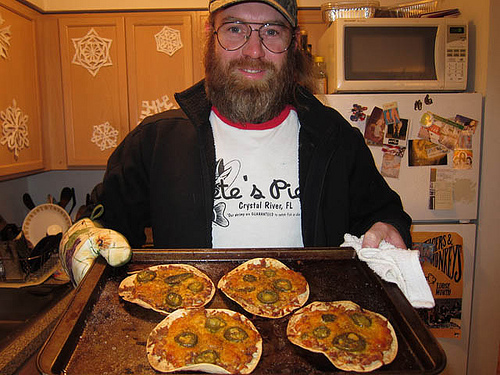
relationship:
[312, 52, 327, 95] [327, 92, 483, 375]
bottle sitting on top fridge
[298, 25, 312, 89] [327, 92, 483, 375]
bottle sitting on top fridge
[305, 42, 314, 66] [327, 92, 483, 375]
bottle sitting on top fridge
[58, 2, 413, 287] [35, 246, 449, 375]
man holding pan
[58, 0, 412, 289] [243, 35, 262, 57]
man has nose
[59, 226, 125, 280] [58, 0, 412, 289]
hand of man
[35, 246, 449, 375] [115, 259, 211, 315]
pan with pizza toritlla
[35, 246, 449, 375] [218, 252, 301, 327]
pan with pizza toritlla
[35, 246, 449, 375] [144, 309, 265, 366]
pan with pizza toritlla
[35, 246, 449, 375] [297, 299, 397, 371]
pan with pizza toritlla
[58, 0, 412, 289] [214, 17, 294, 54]
man wearing glasses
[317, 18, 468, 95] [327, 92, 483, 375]
microwave on top of fridge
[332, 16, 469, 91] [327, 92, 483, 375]
microwave sitting on fridge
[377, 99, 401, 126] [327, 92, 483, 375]
magnet stuck on fridge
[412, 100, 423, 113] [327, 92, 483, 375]
magnet stuck on fridge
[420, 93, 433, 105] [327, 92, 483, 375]
magnet stuck on fridge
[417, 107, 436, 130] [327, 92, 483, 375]
magnet stuck on fridge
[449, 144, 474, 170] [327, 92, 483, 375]
magnet stuck on fridge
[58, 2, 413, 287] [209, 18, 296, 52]
man wearing glasses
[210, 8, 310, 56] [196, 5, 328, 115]
glasses on head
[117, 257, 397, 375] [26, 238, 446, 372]
cookie sheet on pan